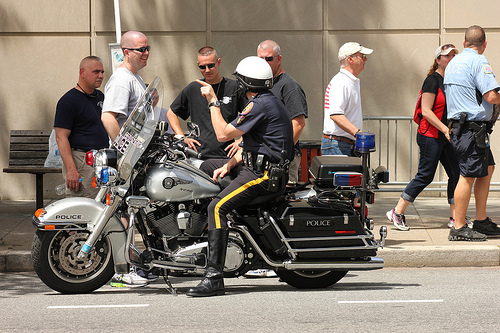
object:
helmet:
[234, 55, 274, 91]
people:
[387, 45, 477, 230]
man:
[101, 28, 151, 149]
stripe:
[208, 173, 280, 231]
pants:
[191, 159, 297, 272]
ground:
[441, 142, 453, 181]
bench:
[3, 128, 63, 209]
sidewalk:
[0, 194, 499, 272]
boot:
[186, 265, 225, 298]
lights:
[97, 167, 113, 190]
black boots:
[183, 226, 231, 298]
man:
[54, 55, 110, 196]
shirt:
[53, 87, 109, 151]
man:
[186, 55, 298, 298]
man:
[318, 37, 375, 160]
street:
[0, 200, 497, 330]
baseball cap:
[335, 40, 373, 63]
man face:
[349, 53, 370, 74]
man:
[169, 45, 234, 155]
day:
[0, 0, 499, 333]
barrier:
[355, 110, 458, 192]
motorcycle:
[32, 78, 391, 295]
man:
[243, 39, 306, 149]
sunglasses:
[127, 46, 147, 53]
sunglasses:
[196, 60, 216, 70]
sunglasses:
[263, 57, 277, 64]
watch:
[208, 98, 222, 109]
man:
[443, 24, 498, 240]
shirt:
[171, 77, 246, 162]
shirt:
[321, 66, 366, 143]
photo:
[0, 0, 499, 333]